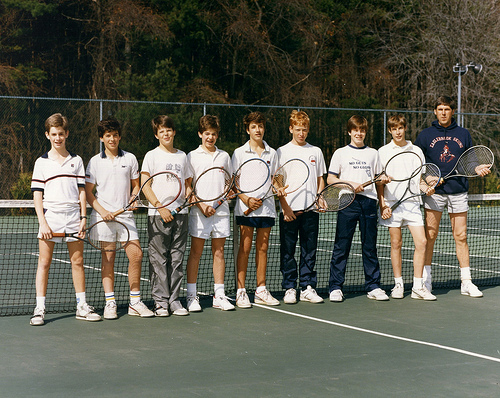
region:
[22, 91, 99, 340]
boy holding tennis racket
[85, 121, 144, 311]
boy holding tennis racket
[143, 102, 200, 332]
boy holding tennis racket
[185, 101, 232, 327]
boy holding tennis racket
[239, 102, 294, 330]
boy holding tennis racket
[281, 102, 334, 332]
boy holding tennis racket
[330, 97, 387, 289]
boy holding tennis racket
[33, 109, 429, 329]
eight boys standing next to each other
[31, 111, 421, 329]
eight boys holding tennis rackets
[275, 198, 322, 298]
a boy wearing blue jeans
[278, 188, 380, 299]
two boys wearing blue jeans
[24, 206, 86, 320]
a boy wearing white shorts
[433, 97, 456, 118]
a man with brown hair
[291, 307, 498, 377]
white line on a tennis court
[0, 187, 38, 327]
a tennis net on a court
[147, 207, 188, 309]
a boy wearing grey pants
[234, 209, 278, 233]
a boy wearing black shorts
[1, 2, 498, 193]
trees behind court fence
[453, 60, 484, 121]
light on top of pole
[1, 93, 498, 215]
poles on chain link fence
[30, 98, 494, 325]
tennis players posing for photo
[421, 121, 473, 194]
hooded sweatshirt with emblem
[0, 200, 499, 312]
black string of net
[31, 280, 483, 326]
white shoes on feet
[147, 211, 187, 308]
long gray pair of pants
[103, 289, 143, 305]
white socks with stripes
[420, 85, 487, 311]
man wearing blue sweatshirt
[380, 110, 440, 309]
boy wearing white shirt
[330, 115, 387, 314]
boy wearing blue pants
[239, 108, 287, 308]
boy wearing blue shorts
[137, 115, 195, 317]
boy wearing gray pants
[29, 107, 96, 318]
boy wearing white shirt with red stripe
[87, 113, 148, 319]
boy holding tennis racket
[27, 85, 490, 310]
boys standing in front of net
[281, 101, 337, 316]
boy with red hair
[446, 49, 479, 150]
light on tennis court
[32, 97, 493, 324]
tennis players standing in a row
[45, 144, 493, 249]
rackets in player's hands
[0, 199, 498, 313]
black strings of net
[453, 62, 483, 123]
light on metal pole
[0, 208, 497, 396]
white lines on court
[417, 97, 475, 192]
man in hooded sweatshirt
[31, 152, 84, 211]
shirt with horizontal stripe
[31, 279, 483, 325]
white sneakers on feet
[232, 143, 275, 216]
shirt with open collar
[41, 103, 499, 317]
tennis team posing in white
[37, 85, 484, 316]
tennis team posing in white with their coach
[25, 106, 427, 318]
eight boys on a team